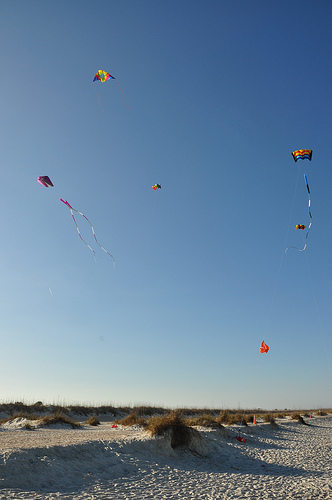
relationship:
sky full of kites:
[1, 1, 331, 403] [1, 62, 317, 359]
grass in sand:
[0, 400, 332, 436] [0, 411, 331, 498]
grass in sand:
[116, 413, 146, 426] [0, 411, 331, 498]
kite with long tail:
[285, 149, 312, 257] [288, 166, 324, 263]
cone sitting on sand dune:
[243, 389, 268, 425] [6, 416, 328, 498]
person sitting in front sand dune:
[234, 428, 244, 444] [6, 416, 328, 498]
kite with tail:
[93, 69, 130, 113] [57, 192, 118, 268]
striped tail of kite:
[60, 193, 120, 274] [35, 172, 55, 189]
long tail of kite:
[285, 174, 312, 255] [288, 143, 317, 168]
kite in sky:
[38, 176, 116, 266] [1, 1, 331, 403]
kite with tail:
[277, 147, 316, 256] [281, 163, 316, 261]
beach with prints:
[0, 410, 331, 499] [230, 462, 270, 471]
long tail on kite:
[285, 174, 312, 255] [289, 144, 316, 165]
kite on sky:
[285, 149, 312, 257] [206, 113, 259, 185]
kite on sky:
[148, 180, 163, 189] [206, 113, 259, 185]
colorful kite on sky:
[260, 340, 269, 353] [206, 113, 259, 185]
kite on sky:
[90, 66, 117, 86] [206, 113, 259, 185]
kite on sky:
[33, 169, 57, 189] [206, 113, 259, 185]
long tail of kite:
[285, 174, 312, 255] [87, 65, 128, 93]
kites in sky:
[28, 60, 329, 362] [1, 1, 331, 403]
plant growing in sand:
[86, 415, 102, 427] [0, 427, 147, 462]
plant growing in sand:
[0, 400, 332, 436] [0, 427, 147, 462]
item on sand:
[251, 414, 260, 430] [0, 411, 331, 498]